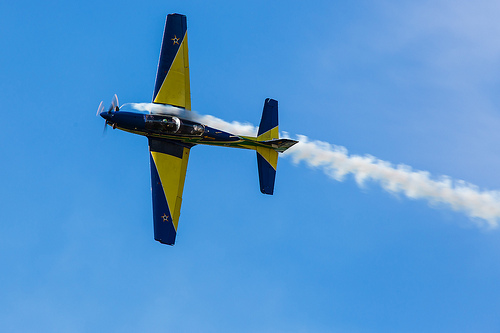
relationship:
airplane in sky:
[96, 11, 299, 247] [1, 1, 484, 331]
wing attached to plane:
[152, 11, 192, 111] [94, 10, 297, 247]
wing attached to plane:
[145, 135, 191, 247] [94, 10, 297, 247]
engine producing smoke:
[110, 104, 257, 154] [119, 100, 484, 235]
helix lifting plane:
[94, 102, 109, 114] [94, 10, 297, 247]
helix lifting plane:
[105, 94, 119, 112] [94, 10, 297, 247]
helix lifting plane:
[100, 111, 110, 133] [94, 10, 297, 247]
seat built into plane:
[152, 114, 177, 132] [94, 10, 297, 247]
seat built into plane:
[180, 116, 204, 137] [94, 10, 297, 247]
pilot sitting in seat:
[157, 117, 168, 125] [153, 115, 179, 135]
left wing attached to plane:
[146, 135, 193, 245] [94, 10, 297, 247]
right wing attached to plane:
[150, 10, 192, 108] [94, 10, 297, 247]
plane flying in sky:
[94, 10, 297, 247] [1, 1, 484, 331]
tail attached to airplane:
[255, 96, 299, 196] [96, 11, 299, 247]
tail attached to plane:
[255, 96, 299, 196] [94, 10, 297, 247]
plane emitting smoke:
[94, 10, 297, 247] [119, 100, 484, 235]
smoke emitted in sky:
[119, 100, 484, 235] [1, 1, 484, 331]